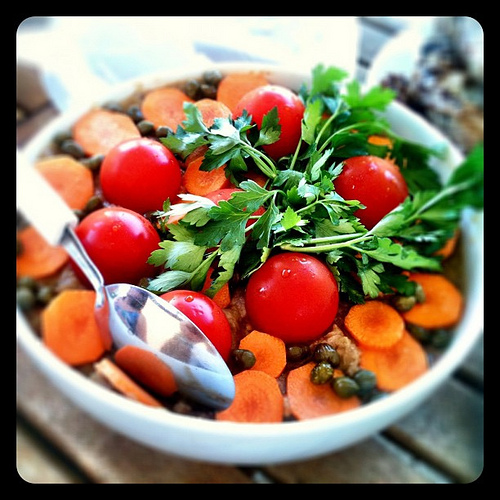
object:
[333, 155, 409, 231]
tomato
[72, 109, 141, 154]
carrots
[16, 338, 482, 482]
boards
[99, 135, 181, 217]
tomato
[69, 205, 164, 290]
tomato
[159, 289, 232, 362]
tomato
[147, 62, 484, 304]
green leaves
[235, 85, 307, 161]
tomato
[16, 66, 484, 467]
bowl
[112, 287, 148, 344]
people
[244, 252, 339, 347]
fruit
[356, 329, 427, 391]
vegetable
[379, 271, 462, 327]
vegetable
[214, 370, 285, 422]
vegetable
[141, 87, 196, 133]
vegetable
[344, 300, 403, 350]
orange carrots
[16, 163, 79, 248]
handle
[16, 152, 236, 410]
spoon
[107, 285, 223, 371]
reflection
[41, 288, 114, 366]
carrot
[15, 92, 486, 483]
table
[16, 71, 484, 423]
food